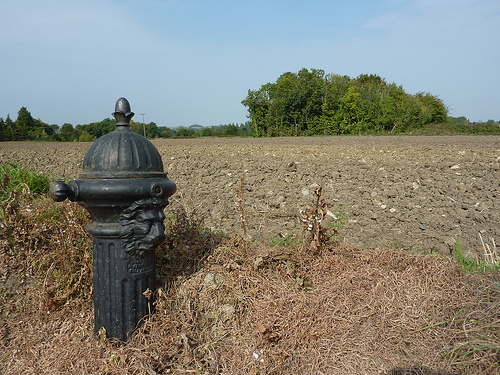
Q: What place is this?
A: It is a farm.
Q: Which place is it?
A: It is a farm.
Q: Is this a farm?
A: Yes, it is a farm.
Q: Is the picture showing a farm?
A: Yes, it is showing a farm.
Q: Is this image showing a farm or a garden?
A: It is showing a farm.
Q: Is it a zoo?
A: No, it is a farm.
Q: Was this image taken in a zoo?
A: No, the picture was taken in a farm.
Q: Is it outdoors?
A: Yes, it is outdoors.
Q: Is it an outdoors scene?
A: Yes, it is outdoors.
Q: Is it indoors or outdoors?
A: It is outdoors.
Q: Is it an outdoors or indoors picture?
A: It is outdoors.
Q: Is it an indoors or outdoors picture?
A: It is outdoors.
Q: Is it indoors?
A: No, it is outdoors.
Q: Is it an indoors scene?
A: No, it is outdoors.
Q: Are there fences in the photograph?
A: No, there are no fences.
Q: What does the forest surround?
A: The forest surrounds the farm.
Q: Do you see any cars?
A: No, there are no cars.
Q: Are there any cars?
A: No, there are no cars.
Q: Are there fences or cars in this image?
A: No, there are no cars or fences.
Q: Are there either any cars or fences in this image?
A: No, there are no cars or fences.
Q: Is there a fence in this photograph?
A: No, there are no fences.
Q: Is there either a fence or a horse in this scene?
A: No, there are no fences or horses.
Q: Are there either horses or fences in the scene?
A: No, there are no fences or horses.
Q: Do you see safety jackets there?
A: No, there are no safety jackets.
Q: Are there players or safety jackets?
A: No, there are no safety jackets or players.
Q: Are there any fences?
A: No, there are no fences.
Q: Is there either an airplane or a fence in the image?
A: No, there are no fences or airplanes.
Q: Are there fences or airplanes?
A: No, there are no fences or airplanes.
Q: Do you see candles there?
A: No, there are no candles.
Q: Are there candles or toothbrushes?
A: No, there are no candles or toothbrushes.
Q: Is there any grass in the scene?
A: Yes, there is grass.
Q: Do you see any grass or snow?
A: Yes, there is grass.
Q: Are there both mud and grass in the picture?
A: No, there is grass but no mud.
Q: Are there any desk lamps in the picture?
A: No, there are no desk lamps.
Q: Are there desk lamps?
A: No, there are no desk lamps.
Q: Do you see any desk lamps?
A: No, there are no desk lamps.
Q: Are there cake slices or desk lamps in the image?
A: No, there are no desk lamps or cake slices.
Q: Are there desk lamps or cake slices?
A: No, there are no desk lamps or cake slices.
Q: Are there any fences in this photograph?
A: No, there are no fences.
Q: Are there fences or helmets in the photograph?
A: No, there are no fences or helmets.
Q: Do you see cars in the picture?
A: No, there are no cars.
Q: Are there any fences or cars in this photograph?
A: No, there are no cars or fences.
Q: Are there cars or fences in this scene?
A: No, there are no cars or fences.